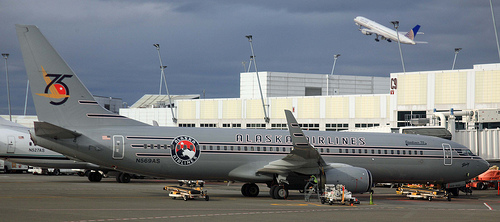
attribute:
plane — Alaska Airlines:
[228, 130, 371, 161]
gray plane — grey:
[30, 58, 470, 189]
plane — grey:
[16, 24, 491, 187]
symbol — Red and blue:
[169, 127, 196, 167]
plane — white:
[346, 10, 446, 64]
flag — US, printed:
[99, 132, 113, 142]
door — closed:
[105, 126, 130, 166]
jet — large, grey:
[19, 21, 486, 202]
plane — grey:
[8, 53, 498, 202]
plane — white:
[353, 15, 428, 45]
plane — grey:
[12, 20, 484, 202]